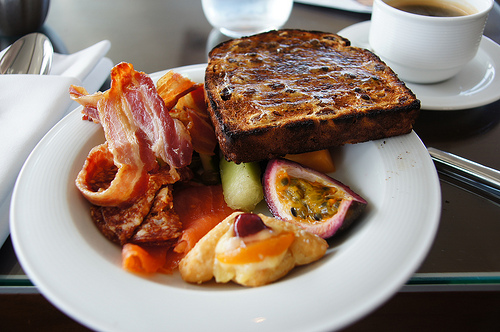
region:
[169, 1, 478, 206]
Browned and buttered toast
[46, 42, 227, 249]
Crispy strips of bacon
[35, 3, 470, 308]
Complete and wholesome breakfast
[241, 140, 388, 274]
Some disgusting looking but probably healthy item in breakfast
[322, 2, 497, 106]
Coffee to compliment the breakfast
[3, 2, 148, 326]
Silverware in a napkin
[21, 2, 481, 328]
White porcelain dishes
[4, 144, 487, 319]
Breakfast on glass table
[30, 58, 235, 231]
Two strips of bacon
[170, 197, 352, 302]
Pastry for desert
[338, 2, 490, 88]
A cup of coffee on a saucer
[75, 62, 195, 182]
A pile of bacon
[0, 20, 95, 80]
A spoon peaking out of a napkin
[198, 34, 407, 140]
A piece of toast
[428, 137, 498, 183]
A knife next to a plate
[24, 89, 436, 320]
A white plate holding a meal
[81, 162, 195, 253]
Salami peeking out from under bacon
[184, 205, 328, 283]
A sweet fan shaped pastry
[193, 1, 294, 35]
A glass of water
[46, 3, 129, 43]
Light reflecting off a table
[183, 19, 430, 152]
burnt toast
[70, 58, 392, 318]
a plate full of food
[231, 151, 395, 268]
fruit in a bowl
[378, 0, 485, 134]
a couple of coffee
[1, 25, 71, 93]
spoon wrapped in a napkin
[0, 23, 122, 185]
a white napkin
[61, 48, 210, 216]
cooked bacon on the plate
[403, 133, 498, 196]
a metal utensil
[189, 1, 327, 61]
a clear glass of water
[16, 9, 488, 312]
a complete breakfast on a table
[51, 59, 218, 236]
the bacon is pink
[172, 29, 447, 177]
the bread is toasted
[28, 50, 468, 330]
the plate is white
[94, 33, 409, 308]
the food is on the plate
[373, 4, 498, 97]
the coffee is on the cup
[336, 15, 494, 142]
the saucer is white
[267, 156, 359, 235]
the dragon fruit has seeds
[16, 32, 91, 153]
the napkin is white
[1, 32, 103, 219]
spoon is inside the napkin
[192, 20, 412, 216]
the bread is brown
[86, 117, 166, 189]
fresh red bacon on plate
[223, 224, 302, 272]
crepe with cherry on top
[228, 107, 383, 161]
french toast that looks fresh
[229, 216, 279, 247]
cherry topping on plate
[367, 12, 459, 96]
cup with coffee in it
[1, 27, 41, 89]
spoon underneath napkin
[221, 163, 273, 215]
celery or cantalope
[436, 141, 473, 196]
bottom edge of eating utensil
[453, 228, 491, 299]
table that plate is on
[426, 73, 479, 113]
plate that mug is on